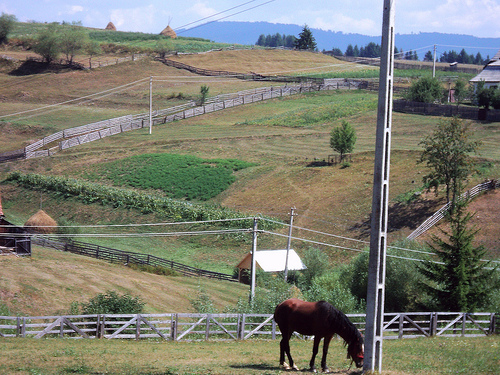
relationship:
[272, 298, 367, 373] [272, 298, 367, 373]
animals looking animals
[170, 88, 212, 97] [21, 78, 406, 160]
bush behind corral fences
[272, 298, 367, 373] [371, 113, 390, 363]
animals at a pole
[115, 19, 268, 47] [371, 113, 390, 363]
wires on pole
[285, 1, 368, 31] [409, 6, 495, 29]
sky full of clouds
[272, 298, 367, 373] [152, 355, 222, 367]
animals in grass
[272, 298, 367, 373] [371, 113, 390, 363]
animals by a pole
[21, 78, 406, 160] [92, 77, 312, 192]
corral fences in a field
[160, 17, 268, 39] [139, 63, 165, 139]
power lines on poles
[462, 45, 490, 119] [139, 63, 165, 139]
building behind poles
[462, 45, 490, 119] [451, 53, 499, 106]
building in distance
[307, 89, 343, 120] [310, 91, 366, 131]
patch of greenery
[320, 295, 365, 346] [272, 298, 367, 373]
mane on a animals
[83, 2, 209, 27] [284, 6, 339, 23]
white clouds in blue sky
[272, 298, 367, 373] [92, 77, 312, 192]
animals grazing in field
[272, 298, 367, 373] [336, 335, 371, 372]
animals horse grazing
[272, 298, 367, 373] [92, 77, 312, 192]
animals in field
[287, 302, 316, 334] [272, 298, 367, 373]
brown large animals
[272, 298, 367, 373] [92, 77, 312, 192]
animals grazin in field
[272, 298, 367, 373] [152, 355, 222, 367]
animals eating grass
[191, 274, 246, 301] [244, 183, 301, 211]
short green and brown grass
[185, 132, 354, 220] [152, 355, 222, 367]
green and brown grass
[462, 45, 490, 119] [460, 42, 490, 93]
small barn with yellow roof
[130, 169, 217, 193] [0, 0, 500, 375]
green vegetation in an field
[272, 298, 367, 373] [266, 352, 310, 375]
animals with white hooves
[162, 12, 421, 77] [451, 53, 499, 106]
mountains in distance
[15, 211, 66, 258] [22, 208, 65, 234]
bale of bale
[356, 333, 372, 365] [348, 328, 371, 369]
white marking on horse's head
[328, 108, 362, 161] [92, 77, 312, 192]
pine tree in field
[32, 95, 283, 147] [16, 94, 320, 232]
corral fences to keep animals